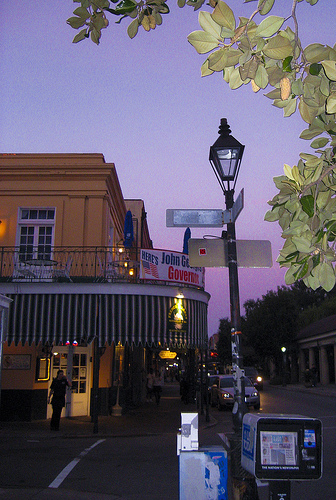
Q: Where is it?
A: This is at the restaurant.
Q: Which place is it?
A: It is a restaurant.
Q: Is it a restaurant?
A: Yes, it is a restaurant.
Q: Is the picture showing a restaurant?
A: Yes, it is showing a restaurant.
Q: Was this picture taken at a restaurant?
A: Yes, it was taken in a restaurant.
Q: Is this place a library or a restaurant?
A: It is a restaurant.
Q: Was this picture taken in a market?
A: No, the picture was taken in a restaurant.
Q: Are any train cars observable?
A: No, there are no train cars.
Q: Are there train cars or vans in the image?
A: No, there are no train cars or vans.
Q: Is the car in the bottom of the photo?
A: Yes, the car is in the bottom of the image.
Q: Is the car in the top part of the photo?
A: No, the car is in the bottom of the image.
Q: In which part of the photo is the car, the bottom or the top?
A: The car is in the bottom of the image.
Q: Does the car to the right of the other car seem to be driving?
A: Yes, the car is driving.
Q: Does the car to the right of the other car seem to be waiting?
A: No, the car is driving.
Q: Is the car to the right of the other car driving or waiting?
A: The car is driving.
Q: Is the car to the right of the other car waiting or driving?
A: The car is driving.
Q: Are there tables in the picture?
A: Yes, there is a table.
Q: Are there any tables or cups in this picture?
A: Yes, there is a table.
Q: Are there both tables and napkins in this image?
A: No, there is a table but no napkins.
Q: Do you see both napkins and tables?
A: No, there is a table but no napkins.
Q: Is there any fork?
A: No, there are no forks.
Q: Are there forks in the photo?
A: No, there are no forks.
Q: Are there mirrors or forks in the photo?
A: No, there are no forks or mirrors.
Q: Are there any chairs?
A: Yes, there is a chair.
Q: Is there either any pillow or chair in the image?
A: Yes, there is a chair.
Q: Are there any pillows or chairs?
A: Yes, there is a chair.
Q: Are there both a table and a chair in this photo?
A: Yes, there are both a chair and a table.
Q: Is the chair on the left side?
A: Yes, the chair is on the left of the image.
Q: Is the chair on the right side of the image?
A: No, the chair is on the left of the image.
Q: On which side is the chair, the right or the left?
A: The chair is on the left of the image.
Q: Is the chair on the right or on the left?
A: The chair is on the left of the image.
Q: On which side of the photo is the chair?
A: The chair is on the left of the image.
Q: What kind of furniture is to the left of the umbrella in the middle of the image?
A: The piece of furniture is a chair.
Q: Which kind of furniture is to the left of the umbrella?
A: The piece of furniture is a chair.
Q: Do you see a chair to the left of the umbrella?
A: Yes, there is a chair to the left of the umbrella.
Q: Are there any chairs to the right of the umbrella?
A: No, the chair is to the left of the umbrella.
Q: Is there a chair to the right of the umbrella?
A: No, the chair is to the left of the umbrella.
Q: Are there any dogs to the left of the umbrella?
A: No, there is a chair to the left of the umbrella.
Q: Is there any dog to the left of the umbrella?
A: No, there is a chair to the left of the umbrella.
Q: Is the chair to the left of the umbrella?
A: Yes, the chair is to the left of the umbrella.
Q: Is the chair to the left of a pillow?
A: No, the chair is to the left of the umbrella.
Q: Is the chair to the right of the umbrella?
A: No, the chair is to the left of the umbrella.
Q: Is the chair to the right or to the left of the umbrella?
A: The chair is to the left of the umbrella.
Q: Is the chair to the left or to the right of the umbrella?
A: The chair is to the left of the umbrella.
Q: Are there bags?
A: No, there are no bags.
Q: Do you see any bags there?
A: No, there are no bags.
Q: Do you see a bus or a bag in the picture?
A: No, there are no bags or buses.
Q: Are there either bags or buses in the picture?
A: No, there are no bags or buses.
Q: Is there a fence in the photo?
A: Yes, there is a fence.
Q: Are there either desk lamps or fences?
A: Yes, there is a fence.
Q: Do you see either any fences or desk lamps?
A: Yes, there is a fence.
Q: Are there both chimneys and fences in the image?
A: No, there is a fence but no chimneys.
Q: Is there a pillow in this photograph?
A: No, there are no pillows.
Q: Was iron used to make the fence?
A: Yes, the fence is made of iron.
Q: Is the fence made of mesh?
A: No, the fence is made of iron.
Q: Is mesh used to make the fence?
A: No, the fence is made of iron.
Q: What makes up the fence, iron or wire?
A: The fence is made of iron.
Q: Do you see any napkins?
A: No, there are no napkins.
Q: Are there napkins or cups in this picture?
A: No, there are no napkins or cups.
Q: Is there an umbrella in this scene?
A: Yes, there is an umbrella.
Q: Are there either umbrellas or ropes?
A: Yes, there is an umbrella.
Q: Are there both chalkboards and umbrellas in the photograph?
A: No, there is an umbrella but no chalkboards.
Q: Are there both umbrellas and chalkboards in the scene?
A: No, there is an umbrella but no chalkboards.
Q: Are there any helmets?
A: No, there are no helmets.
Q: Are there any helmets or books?
A: No, there are no helmets or books.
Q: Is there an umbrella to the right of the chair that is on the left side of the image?
A: Yes, there is an umbrella to the right of the chair.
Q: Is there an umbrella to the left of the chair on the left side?
A: No, the umbrella is to the right of the chair.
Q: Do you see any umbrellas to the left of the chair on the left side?
A: No, the umbrella is to the right of the chair.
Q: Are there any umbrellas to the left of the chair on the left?
A: No, the umbrella is to the right of the chair.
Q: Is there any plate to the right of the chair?
A: No, there is an umbrella to the right of the chair.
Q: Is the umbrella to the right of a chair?
A: Yes, the umbrella is to the right of a chair.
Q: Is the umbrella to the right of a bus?
A: No, the umbrella is to the right of a chair.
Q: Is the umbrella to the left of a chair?
A: No, the umbrella is to the right of a chair.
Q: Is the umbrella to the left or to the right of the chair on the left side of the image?
A: The umbrella is to the right of the chair.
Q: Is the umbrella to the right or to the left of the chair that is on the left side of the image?
A: The umbrella is to the right of the chair.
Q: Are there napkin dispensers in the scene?
A: No, there are no napkin dispensers.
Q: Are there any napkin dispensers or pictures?
A: No, there are no napkin dispensers or pictures.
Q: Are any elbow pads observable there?
A: No, there are no elbow pads.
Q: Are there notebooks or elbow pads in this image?
A: No, there are no elbow pads or notebooks.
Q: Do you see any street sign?
A: Yes, there is a street sign.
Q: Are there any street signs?
A: Yes, there is a street sign.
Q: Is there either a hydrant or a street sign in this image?
A: Yes, there is a street sign.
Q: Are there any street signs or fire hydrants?
A: Yes, there is a street sign.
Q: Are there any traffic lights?
A: No, there are no traffic lights.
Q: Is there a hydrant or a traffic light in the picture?
A: No, there are no traffic lights or fire hydrants.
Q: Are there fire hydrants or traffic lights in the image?
A: No, there are no traffic lights or fire hydrants.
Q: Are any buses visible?
A: No, there are no buses.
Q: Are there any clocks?
A: No, there are no clocks.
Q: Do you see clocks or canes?
A: No, there are no clocks or canes.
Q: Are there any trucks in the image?
A: No, there are no trucks.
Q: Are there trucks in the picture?
A: No, there are no trucks.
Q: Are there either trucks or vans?
A: No, there are no trucks or vans.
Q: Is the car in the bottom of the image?
A: Yes, the car is in the bottom of the image.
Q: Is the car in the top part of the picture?
A: No, the car is in the bottom of the image.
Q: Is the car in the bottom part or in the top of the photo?
A: The car is in the bottom of the image.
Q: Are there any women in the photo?
A: Yes, there is a woman.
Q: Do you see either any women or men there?
A: Yes, there is a woman.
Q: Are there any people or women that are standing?
A: Yes, the woman is standing.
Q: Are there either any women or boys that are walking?
A: Yes, the woman is walking.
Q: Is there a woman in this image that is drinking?
A: Yes, there is a woman that is drinking.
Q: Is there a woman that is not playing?
A: Yes, there is a woman that is drinking.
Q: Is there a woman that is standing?
A: Yes, there is a woman that is standing.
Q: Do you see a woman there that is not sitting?
A: Yes, there is a woman that is standing .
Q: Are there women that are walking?
A: Yes, there is a woman that is walking.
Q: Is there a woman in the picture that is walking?
A: Yes, there is a woman that is walking.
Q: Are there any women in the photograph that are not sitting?
A: Yes, there is a woman that is walking.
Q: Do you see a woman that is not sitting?
A: Yes, there is a woman that is walking .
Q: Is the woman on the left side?
A: Yes, the woman is on the left of the image.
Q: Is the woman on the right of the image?
A: No, the woman is on the left of the image.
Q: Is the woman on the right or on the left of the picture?
A: The woman is on the left of the image.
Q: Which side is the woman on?
A: The woman is on the left of the image.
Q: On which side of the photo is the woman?
A: The woman is on the left of the image.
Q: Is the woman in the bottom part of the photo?
A: Yes, the woman is in the bottom of the image.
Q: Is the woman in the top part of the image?
A: No, the woman is in the bottom of the image.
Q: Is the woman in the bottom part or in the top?
A: The woman is in the bottom of the image.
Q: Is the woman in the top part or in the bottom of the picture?
A: The woman is in the bottom of the image.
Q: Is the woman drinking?
A: Yes, the woman is drinking.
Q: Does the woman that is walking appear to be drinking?
A: Yes, the woman is drinking.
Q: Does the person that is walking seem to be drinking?
A: Yes, the woman is drinking.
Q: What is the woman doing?
A: The woman is drinking.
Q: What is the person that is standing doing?
A: The woman is drinking.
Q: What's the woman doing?
A: The woman is drinking.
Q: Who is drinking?
A: The woman is drinking.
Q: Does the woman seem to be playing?
A: No, the woman is drinking.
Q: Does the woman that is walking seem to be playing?
A: No, the woman is drinking.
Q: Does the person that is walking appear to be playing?
A: No, the woman is drinking.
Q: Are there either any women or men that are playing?
A: No, there is a woman but she is drinking.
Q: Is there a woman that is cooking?
A: No, there is a woman but she is drinking.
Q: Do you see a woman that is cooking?
A: No, there is a woman but she is drinking.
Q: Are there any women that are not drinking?
A: No, there is a woman but she is drinking.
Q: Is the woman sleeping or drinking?
A: The woman is drinking.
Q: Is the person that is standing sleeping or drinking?
A: The woman is drinking.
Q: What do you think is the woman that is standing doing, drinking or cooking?
A: The woman is drinking.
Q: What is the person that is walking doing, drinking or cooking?
A: The woman is drinking.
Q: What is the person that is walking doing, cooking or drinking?
A: The woman is drinking.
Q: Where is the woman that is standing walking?
A: The woman is walking on the sidewalk.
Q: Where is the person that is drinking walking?
A: The woman is walking on the sidewalk.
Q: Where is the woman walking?
A: The woman is walking on the sidewalk.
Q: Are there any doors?
A: Yes, there is a door.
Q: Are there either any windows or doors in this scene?
A: Yes, there is a door.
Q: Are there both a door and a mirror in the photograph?
A: No, there is a door but no mirrors.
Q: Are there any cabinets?
A: No, there are no cabinets.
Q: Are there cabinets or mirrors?
A: No, there are no cabinets or mirrors.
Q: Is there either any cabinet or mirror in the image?
A: No, there are no cabinets or mirrors.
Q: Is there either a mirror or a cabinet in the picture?
A: No, there are no cabinets or mirrors.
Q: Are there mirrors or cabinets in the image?
A: No, there are no cabinets or mirrors.